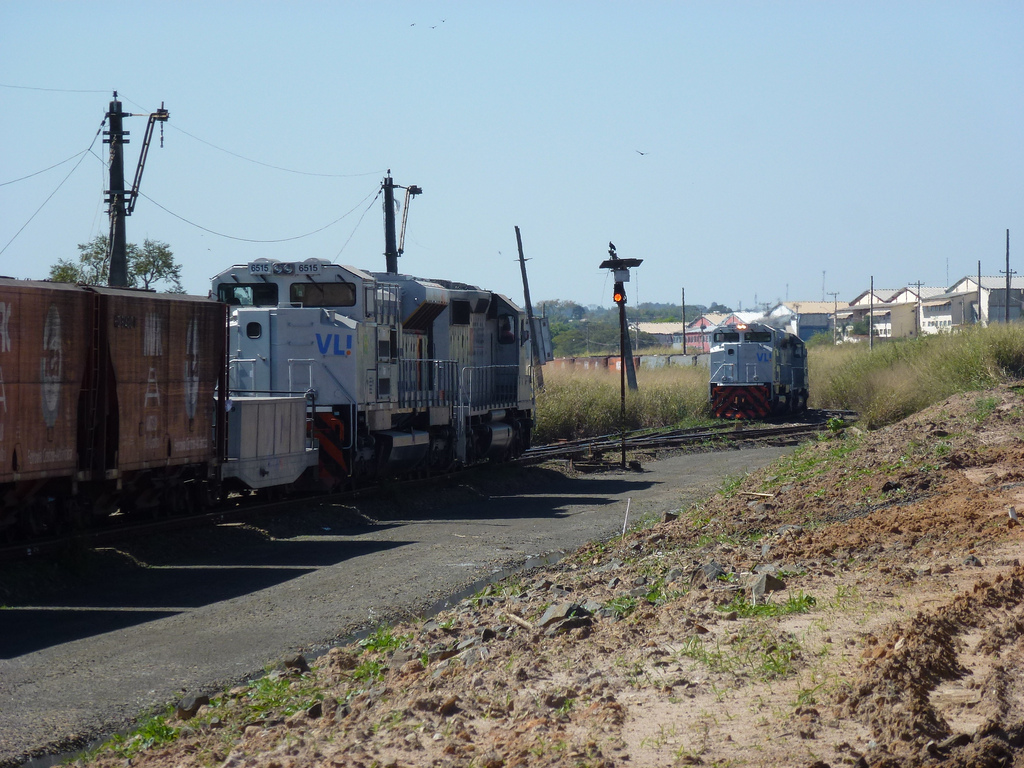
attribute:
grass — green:
[810, 320, 1020, 422]